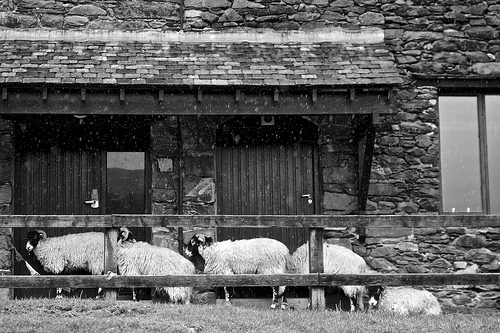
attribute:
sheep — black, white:
[182, 230, 293, 312]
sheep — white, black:
[108, 234, 198, 306]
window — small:
[103, 150, 145, 239]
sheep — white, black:
[107, 227, 194, 307]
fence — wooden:
[0, 212, 499, 310]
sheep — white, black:
[3, 129, 363, 327]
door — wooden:
[75, 144, 190, 287]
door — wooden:
[219, 125, 319, 252]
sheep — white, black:
[160, 213, 341, 331]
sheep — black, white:
[354, 273, 455, 313]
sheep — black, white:
[25, 226, 129, 287]